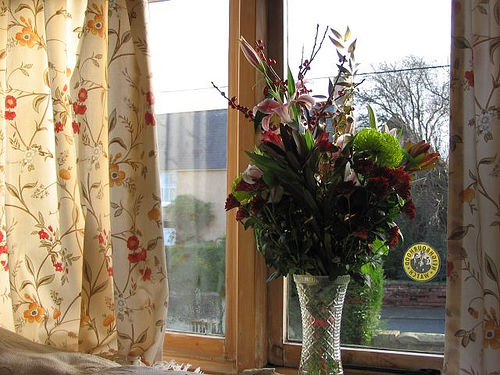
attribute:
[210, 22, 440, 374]
plant — green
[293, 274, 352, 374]
vase — glass, crystal, clear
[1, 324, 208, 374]
cloth — brown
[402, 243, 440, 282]
circle — yellow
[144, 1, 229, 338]
window — closed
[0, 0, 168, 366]
curtains — cream colored, white, hanging, red, orange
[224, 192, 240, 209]
carnations — pink, red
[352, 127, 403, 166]
flower — shiny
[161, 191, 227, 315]
hedge — beatiful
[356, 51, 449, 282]
tree — leafless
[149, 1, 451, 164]
sky — white, cloudy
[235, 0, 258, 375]
wall — white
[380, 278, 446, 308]
wall — brick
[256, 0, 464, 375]
window frame — brown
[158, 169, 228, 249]
building — yellow